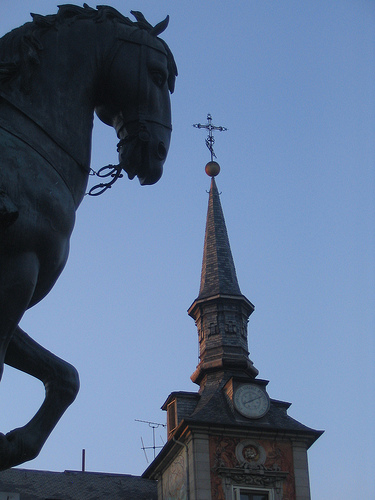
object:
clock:
[233, 382, 272, 420]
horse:
[0, 3, 179, 475]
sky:
[0, 0, 374, 498]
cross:
[192, 112, 229, 161]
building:
[141, 113, 325, 498]